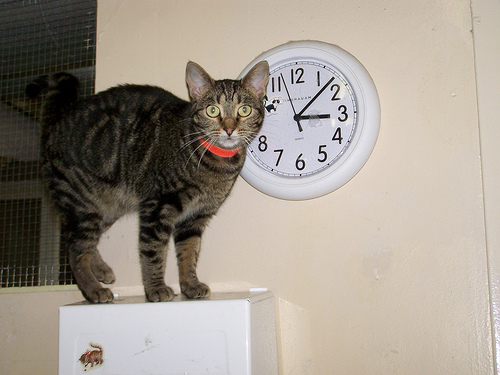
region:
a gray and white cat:
[25, 55, 273, 303]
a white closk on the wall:
[229, 38, 383, 198]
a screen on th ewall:
[4, 10, 100, 293]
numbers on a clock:
[275, 68, 348, 180]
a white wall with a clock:
[265, 0, 482, 367]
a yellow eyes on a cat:
[199, 103, 254, 126]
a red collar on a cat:
[198, 137, 234, 159]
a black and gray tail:
[21, 60, 82, 137]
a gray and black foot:
[139, 280, 179, 310]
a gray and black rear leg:
[70, 233, 111, 310]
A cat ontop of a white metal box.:
[37, 57, 277, 372]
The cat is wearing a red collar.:
[192, 136, 242, 159]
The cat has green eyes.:
[200, 101, 256, 117]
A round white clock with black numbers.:
[225, 38, 380, 200]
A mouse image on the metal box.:
[72, 338, 108, 371]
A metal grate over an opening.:
[0, 6, 95, 281]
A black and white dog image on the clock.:
[266, 91, 279, 116]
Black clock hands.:
[293, 70, 334, 118]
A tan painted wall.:
[0, 5, 496, 372]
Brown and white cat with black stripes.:
[33, 60, 266, 302]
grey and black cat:
[21, 61, 268, 301]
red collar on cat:
[193, 133, 243, 160]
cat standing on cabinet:
[23, 60, 269, 303]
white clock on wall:
[232, 38, 382, 200]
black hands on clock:
[295, 74, 336, 125]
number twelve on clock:
[290, 67, 305, 82]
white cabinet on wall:
[56, 291, 276, 371]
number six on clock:
[295, 151, 302, 168]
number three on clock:
[336, 105, 346, 120]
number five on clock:
[316, 145, 326, 162]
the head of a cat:
[179, 54, 276, 161]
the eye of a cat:
[203, 101, 221, 121]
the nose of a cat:
[221, 123, 237, 137]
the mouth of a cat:
[218, 134, 240, 144]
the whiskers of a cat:
[173, 122, 221, 177]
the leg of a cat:
[135, 208, 174, 285]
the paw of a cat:
[141, 276, 181, 304]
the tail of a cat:
[18, 63, 84, 115]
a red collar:
[196, 132, 246, 167]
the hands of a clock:
[289, 73, 340, 129]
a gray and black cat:
[25, 46, 268, 306]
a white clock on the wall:
[245, 36, 382, 201]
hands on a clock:
[295, 76, 346, 123]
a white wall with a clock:
[273, 17, 472, 302]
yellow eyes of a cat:
[205, 101, 254, 121]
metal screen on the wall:
[1, 8, 70, 285]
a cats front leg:
[136, 216, 179, 303]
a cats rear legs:
[59, 192, 119, 305]